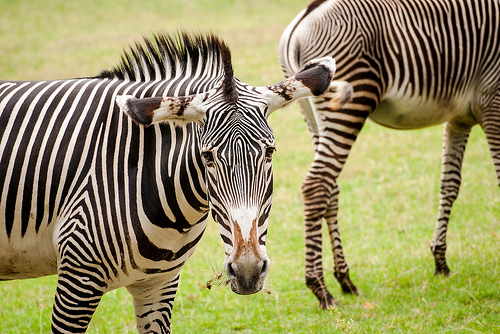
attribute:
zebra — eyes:
[8, 47, 274, 327]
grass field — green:
[0, 5, 499, 332]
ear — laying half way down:
[253, 56, 335, 113]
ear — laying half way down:
[113, 92, 208, 127]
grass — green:
[358, 184, 443, 326]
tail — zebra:
[280, 15, 355, 110]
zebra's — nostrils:
[2, 28, 352, 333]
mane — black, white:
[123, 25, 237, 92]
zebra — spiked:
[94, 25, 251, 98]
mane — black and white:
[106, 32, 233, 80]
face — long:
[186, 82, 278, 296]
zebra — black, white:
[275, 0, 498, 308]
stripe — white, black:
[391, 16, 414, 94]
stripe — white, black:
[399, 0, 433, 106]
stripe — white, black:
[417, 0, 432, 35]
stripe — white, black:
[447, 1, 459, 106]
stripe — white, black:
[440, 168, 461, 177]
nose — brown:
[230, 212, 272, 276]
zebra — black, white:
[1, 27, 336, 331]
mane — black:
[99, 27, 239, 107]